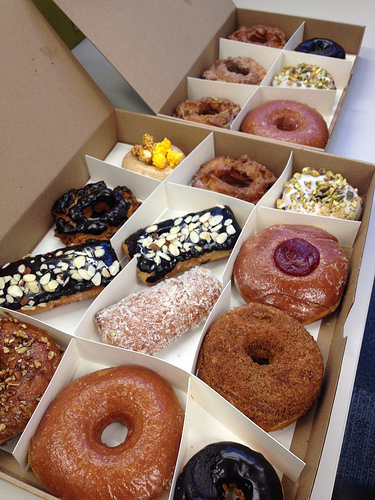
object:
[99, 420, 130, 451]
hole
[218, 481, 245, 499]
hole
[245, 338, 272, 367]
hole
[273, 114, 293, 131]
hole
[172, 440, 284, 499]
donut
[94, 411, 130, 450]
edge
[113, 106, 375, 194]
edge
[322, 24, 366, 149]
edge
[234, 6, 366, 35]
edge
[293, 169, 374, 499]
edge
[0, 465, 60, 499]
edge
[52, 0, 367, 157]
box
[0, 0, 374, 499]
box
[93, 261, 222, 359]
topping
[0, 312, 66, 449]
donut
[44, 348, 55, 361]
topping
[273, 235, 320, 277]
jam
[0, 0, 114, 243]
cover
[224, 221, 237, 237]
nut flakes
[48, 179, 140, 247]
donut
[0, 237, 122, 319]
donuts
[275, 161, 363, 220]
donut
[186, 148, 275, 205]
donut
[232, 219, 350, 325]
donut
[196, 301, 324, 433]
donut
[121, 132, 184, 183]
donut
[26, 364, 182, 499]
donut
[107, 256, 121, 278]
nuts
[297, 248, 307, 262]
part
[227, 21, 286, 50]
donut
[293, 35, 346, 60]
donut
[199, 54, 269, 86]
donut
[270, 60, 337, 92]
donut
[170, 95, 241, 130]
donut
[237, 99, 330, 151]
donut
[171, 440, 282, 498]
icing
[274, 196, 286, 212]
dry fruit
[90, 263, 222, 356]
donut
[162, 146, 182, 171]
topping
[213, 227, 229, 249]
nut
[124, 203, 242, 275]
chocolate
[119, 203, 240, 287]
donut